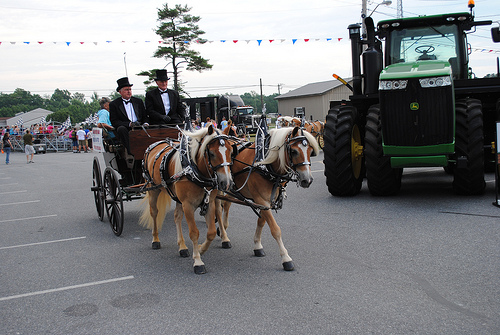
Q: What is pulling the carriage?
A: Two brown horses pulling a carriage.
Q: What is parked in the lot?
A: Green tractor parked in lot.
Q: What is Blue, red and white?
A: The pennant banner Blue, red and white.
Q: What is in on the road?
A: There are two horses on the road.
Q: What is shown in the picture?
A: A green john deere tractor.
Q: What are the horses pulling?
A: There are Two horses pulling a carriage.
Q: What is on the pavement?
A: White lines on the pavement.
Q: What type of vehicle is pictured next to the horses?
A: Tractor.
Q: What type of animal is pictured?
A: Horse.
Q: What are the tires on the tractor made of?
A: Rubber.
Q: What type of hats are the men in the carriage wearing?
A: Top hats.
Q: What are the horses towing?
A: Carriage.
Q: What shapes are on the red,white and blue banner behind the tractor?
A: Triangles.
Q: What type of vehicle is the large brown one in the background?
A: Tractor trailer.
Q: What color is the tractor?
A: Green.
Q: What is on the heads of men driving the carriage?
A: Top hats.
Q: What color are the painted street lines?
A: White.